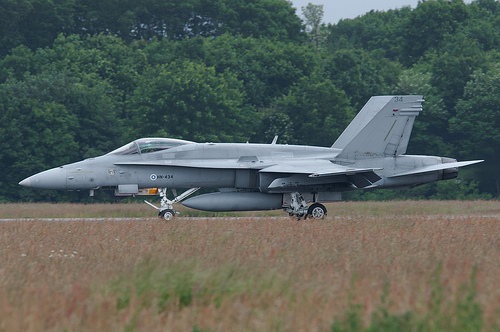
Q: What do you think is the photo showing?
A: It is showing a field.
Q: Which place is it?
A: It is a field.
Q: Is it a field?
A: Yes, it is a field.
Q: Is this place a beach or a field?
A: It is a field.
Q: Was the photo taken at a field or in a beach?
A: It was taken at a field.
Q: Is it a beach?
A: No, it is a field.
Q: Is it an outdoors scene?
A: Yes, it is outdoors.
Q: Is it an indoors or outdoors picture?
A: It is outdoors.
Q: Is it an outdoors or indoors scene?
A: It is outdoors.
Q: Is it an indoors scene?
A: No, it is outdoors.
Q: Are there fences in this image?
A: No, there are no fences.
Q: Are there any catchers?
A: No, there are no catchers.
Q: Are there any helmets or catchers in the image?
A: No, there are no catchers or helmets.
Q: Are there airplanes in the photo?
A: Yes, there is an airplane.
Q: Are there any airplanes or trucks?
A: Yes, there is an airplane.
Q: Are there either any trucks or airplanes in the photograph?
A: Yes, there is an airplane.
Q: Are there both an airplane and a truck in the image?
A: No, there is an airplane but no trucks.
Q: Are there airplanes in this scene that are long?
A: Yes, there is a long airplane.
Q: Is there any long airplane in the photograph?
A: Yes, there is a long airplane.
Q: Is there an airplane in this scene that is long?
A: Yes, there is an airplane that is long.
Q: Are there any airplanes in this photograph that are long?
A: Yes, there is an airplane that is long.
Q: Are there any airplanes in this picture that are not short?
A: Yes, there is a long airplane.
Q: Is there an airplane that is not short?
A: Yes, there is a long airplane.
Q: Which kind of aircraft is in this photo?
A: The aircraft is an airplane.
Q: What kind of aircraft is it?
A: The aircraft is an airplane.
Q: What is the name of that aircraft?
A: This is an airplane.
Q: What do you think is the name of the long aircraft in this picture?
A: The aircraft is an airplane.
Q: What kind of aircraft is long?
A: The aircraft is an airplane.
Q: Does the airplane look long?
A: Yes, the airplane is long.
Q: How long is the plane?
A: The plane is long.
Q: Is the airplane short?
A: No, the airplane is long.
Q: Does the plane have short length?
A: No, the plane is long.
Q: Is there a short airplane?
A: No, there is an airplane but it is long.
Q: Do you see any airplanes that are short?
A: No, there is an airplane but it is long.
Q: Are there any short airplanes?
A: No, there is an airplane but it is long.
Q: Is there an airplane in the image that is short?
A: No, there is an airplane but it is long.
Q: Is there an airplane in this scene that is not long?
A: No, there is an airplane but it is long.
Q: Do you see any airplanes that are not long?
A: No, there is an airplane but it is long.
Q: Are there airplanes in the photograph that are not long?
A: No, there is an airplane but it is long.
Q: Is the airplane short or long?
A: The airplane is long.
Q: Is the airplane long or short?
A: The airplane is long.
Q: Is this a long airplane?
A: Yes, this is a long airplane.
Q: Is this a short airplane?
A: No, this is a long airplane.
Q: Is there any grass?
A: Yes, there is grass.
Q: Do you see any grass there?
A: Yes, there is grass.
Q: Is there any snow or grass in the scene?
A: Yes, there is grass.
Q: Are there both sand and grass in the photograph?
A: No, there is grass but no sand.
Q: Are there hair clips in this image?
A: No, there are no hair clips.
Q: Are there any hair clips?
A: No, there are no hair clips.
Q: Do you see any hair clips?
A: No, there are no hair clips.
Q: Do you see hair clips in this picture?
A: No, there are no hair clips.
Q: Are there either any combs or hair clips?
A: No, there are no hair clips or combs.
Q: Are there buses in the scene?
A: No, there are no buses.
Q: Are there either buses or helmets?
A: No, there are no buses or helmets.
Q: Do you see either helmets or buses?
A: No, there are no buses or helmets.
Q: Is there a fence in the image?
A: No, there are no fences.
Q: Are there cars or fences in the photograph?
A: No, there are no fences or cars.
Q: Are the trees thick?
A: Yes, the trees are thick.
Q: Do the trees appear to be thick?
A: Yes, the trees are thick.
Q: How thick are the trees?
A: The trees are thick.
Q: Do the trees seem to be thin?
A: No, the trees are thick.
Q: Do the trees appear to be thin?
A: No, the trees are thick.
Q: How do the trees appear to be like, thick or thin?
A: The trees are thick.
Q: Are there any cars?
A: No, there are no cars.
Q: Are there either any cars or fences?
A: No, there are no cars or fences.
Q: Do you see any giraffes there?
A: No, there are no giraffes.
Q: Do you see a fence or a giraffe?
A: No, there are no giraffes or fences.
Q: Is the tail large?
A: Yes, the tail is large.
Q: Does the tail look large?
A: Yes, the tail is large.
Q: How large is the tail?
A: The tail is large.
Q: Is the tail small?
A: No, the tail is large.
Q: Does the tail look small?
A: No, the tail is large.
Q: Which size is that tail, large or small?
A: The tail is large.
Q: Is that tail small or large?
A: The tail is large.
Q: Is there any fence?
A: No, there are no fences.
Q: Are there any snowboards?
A: No, there are no snowboards.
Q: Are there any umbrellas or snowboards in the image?
A: No, there are no snowboards or umbrellas.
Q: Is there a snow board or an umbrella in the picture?
A: No, there are no snowboards or umbrellas.